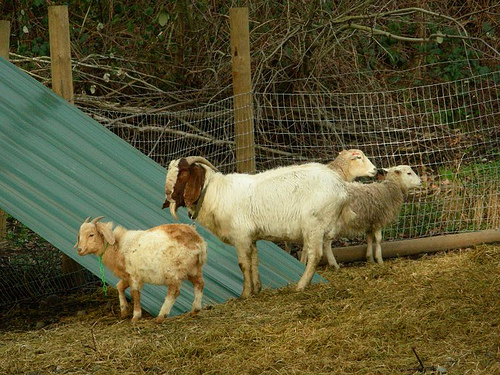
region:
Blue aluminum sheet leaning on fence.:
[3, 68, 146, 214]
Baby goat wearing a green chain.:
[71, 213, 118, 291]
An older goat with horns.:
[154, 155, 350, 230]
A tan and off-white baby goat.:
[66, 217, 211, 317]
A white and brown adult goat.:
[157, 153, 359, 226]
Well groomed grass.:
[58, 300, 461, 350]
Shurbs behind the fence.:
[246, 26, 410, 88]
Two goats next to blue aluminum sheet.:
[55, 150, 264, 332]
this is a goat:
[71, 199, 217, 336]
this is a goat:
[135, 153, 352, 313]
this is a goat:
[313, 141, 385, 179]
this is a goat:
[306, 145, 451, 286]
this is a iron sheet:
[1, 57, 331, 359]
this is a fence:
[3, 57, 489, 252]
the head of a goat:
[51, 207, 114, 273]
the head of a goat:
[145, 145, 210, 216]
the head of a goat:
[331, 142, 377, 184]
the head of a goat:
[387, 150, 437, 217]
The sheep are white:
[69, 94, 312, 361]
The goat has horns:
[57, 197, 284, 326]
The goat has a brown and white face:
[143, 129, 234, 254]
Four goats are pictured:
[102, 142, 457, 311]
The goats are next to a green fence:
[75, 173, 333, 368]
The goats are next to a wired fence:
[295, 127, 445, 277]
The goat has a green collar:
[61, 193, 363, 372]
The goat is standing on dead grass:
[75, 213, 491, 334]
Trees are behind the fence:
[60, 20, 319, 160]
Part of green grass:
[34, 341, 108, 371]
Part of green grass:
[106, 326, 154, 370]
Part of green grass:
[147, 316, 194, 368]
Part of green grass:
[187, 295, 238, 363]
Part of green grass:
[226, 288, 266, 338]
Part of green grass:
[223, 324, 268, 369]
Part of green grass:
[276, 285, 326, 333]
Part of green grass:
[343, 260, 415, 315]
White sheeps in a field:
[60, 56, 399, 352]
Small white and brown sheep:
[63, 201, 203, 348]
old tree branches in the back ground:
[191, 0, 393, 80]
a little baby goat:
[77, 192, 275, 320]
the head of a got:
[153, 145, 262, 227]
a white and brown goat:
[142, 136, 437, 259]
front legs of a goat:
[228, 194, 296, 324]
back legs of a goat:
[279, 198, 365, 299]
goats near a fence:
[277, 63, 497, 265]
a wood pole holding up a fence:
[197, 19, 325, 190]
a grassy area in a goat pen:
[301, 248, 489, 370]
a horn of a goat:
[179, 123, 249, 187]